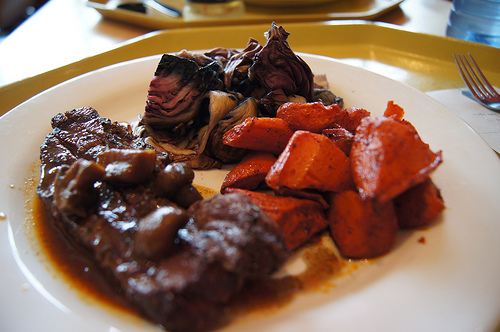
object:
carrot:
[352, 118, 434, 202]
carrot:
[333, 176, 410, 257]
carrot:
[257, 131, 354, 191]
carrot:
[217, 111, 292, 153]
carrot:
[226, 176, 328, 246]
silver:
[454, 54, 499, 101]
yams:
[383, 101, 408, 118]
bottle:
[444, 0, 500, 45]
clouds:
[2, 26, 499, 331]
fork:
[452, 52, 499, 114]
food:
[25, 19, 447, 329]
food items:
[40, 24, 442, 319]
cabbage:
[148, 22, 307, 154]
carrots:
[398, 179, 453, 230]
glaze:
[38, 106, 284, 332]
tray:
[70, 0, 414, 45]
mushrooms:
[61, 157, 108, 221]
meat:
[41, 105, 285, 327]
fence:
[166, 26, 267, 52]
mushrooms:
[151, 163, 206, 214]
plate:
[0, 45, 500, 331]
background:
[0, 0, 499, 29]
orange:
[253, 121, 276, 137]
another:
[36, 106, 294, 331]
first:
[357, 286, 454, 332]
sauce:
[174, 279, 323, 332]